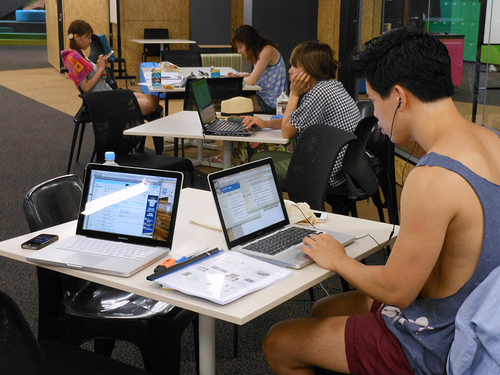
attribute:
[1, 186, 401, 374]
table — white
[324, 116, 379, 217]
chair — black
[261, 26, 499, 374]
person — young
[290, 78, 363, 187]
shirt — black, white, plaid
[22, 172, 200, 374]
chair — empty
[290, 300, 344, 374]
shorts — red, burgundy, maroon, dark red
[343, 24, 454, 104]
hair — black, short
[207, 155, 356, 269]
laptop — opened, open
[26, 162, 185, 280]
laptop — opened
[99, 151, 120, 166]
bottle — plastic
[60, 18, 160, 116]
woman — sitting, young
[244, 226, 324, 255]
keys — black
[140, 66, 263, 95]
table — white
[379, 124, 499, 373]
shirt — blue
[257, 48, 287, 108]
shirt — blue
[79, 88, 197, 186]
chair — black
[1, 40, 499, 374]
floor — carpeted